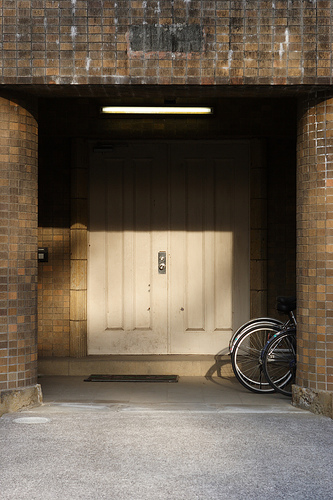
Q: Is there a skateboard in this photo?
A: No, there are no skateboards.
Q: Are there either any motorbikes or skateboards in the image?
A: No, there are no skateboards or motorbikes.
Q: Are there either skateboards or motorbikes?
A: No, there are no skateboards or motorbikes.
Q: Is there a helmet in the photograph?
A: No, there are no helmets.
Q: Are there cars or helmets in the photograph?
A: No, there are no helmets or cars.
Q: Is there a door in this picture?
A: Yes, there is a door.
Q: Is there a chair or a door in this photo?
A: Yes, there is a door.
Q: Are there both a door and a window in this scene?
A: No, there is a door but no windows.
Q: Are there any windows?
A: No, there are no windows.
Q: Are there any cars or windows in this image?
A: No, there are no windows or cars.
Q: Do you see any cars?
A: No, there are no cars.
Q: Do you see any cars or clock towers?
A: No, there are no cars or clock towers.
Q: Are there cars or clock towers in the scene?
A: No, there are no cars or clock towers.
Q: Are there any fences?
A: No, there are no fences.